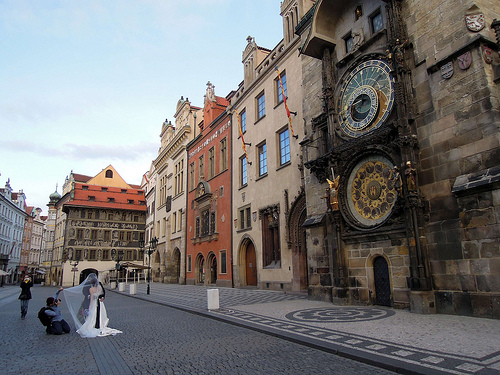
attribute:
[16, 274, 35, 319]
person — standing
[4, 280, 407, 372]
street — stone, clean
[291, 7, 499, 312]
building — stone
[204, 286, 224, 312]
rectangle — white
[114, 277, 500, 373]
sidewalk — decorative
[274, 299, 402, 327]
design — circular, stone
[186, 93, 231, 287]
building — orange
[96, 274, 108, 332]
fabric — black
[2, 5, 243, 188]
sky — blue, cloudless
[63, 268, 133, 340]
couple — married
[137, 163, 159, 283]
building — white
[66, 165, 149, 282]
building — old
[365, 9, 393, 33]
window — glass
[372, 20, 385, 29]
glass — stained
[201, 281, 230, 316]
can — white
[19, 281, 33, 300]
coat — black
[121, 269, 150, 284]
posts — white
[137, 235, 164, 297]
lamp — decorative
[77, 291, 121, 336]
dress — white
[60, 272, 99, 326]
veil — long, flowy